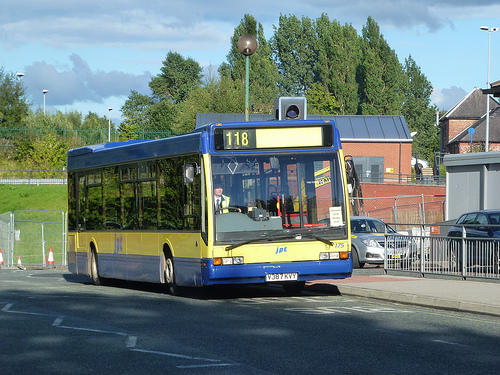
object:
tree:
[315, 8, 402, 118]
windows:
[67, 152, 200, 234]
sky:
[1, 0, 498, 134]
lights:
[318, 250, 350, 261]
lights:
[213, 256, 244, 266]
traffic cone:
[42, 246, 57, 266]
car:
[348, 215, 418, 269]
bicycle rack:
[384, 223, 499, 282]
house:
[437, 87, 500, 154]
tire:
[160, 254, 180, 297]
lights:
[13, 72, 114, 111]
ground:
[362, 145, 402, 181]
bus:
[67, 117, 354, 294]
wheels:
[88, 244, 184, 296]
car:
[446, 211, 500, 275]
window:
[211, 154, 338, 231]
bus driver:
[208, 180, 237, 217]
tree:
[401, 53, 449, 175]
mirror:
[183, 161, 200, 183]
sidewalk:
[341, 271, 500, 317]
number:
[225, 129, 251, 147]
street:
[0, 262, 500, 375]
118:
[226, 130, 249, 146]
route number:
[212, 124, 332, 150]